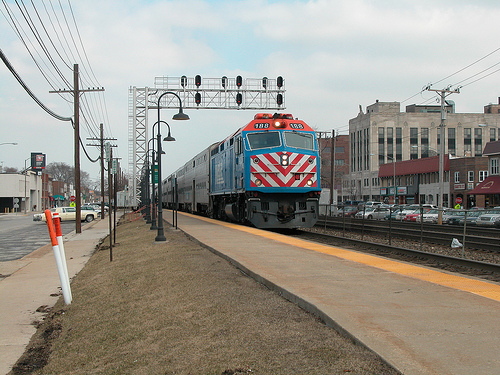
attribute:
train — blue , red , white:
[152, 111, 323, 231]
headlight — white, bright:
[272, 120, 282, 130]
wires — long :
[0, 0, 116, 171]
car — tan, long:
[28, 203, 101, 223]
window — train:
[233, 111, 327, 165]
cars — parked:
[318, 193, 499, 228]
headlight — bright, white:
[306, 171, 318, 188]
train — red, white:
[182, 114, 347, 205]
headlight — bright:
[273, 120, 282, 128]